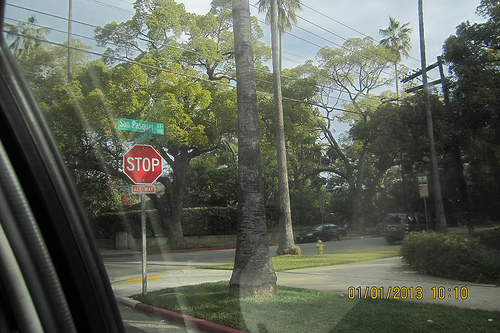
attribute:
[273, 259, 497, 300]
sidewalk — small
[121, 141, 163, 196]
stop sign — red, white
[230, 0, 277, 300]
tree trunk — tall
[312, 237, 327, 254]
fire hydrant — yellow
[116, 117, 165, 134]
sign — green, white